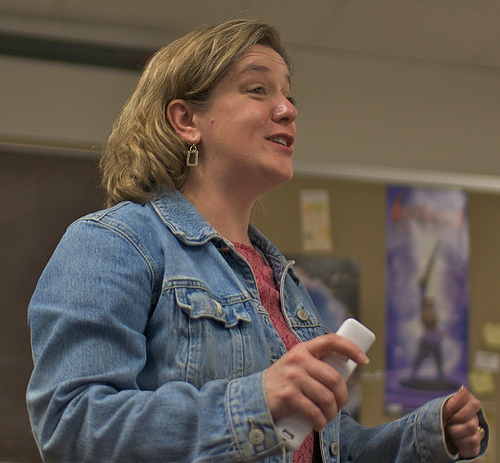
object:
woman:
[26, 18, 490, 463]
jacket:
[26, 183, 491, 463]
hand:
[265, 333, 370, 431]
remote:
[276, 318, 376, 451]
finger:
[453, 426, 485, 449]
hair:
[92, 9, 294, 208]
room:
[0, 0, 500, 462]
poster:
[386, 183, 469, 414]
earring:
[187, 144, 200, 167]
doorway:
[0, 159, 104, 463]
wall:
[365, 60, 457, 149]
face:
[200, 46, 298, 179]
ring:
[477, 426, 485, 438]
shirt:
[227, 239, 314, 462]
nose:
[271, 98, 298, 124]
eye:
[246, 86, 267, 95]